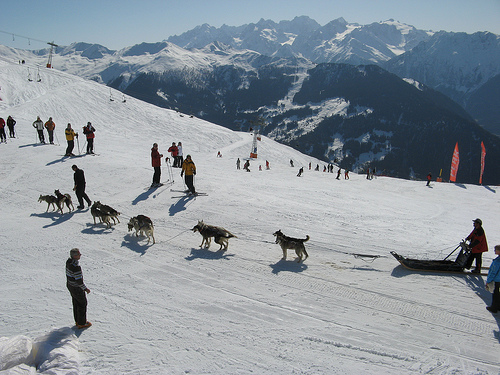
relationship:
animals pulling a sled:
[271, 229, 311, 259] [385, 242, 469, 280]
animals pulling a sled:
[188, 222, 239, 254] [385, 242, 469, 280]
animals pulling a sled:
[271, 229, 311, 259] [390, 250, 462, 274]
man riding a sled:
[462, 218, 486, 275] [390, 243, 472, 272]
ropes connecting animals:
[48, 187, 397, 266] [271, 229, 311, 259]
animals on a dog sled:
[271, 229, 311, 259] [388, 217, 482, 278]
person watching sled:
[64, 247, 98, 326] [391, 246, 472, 272]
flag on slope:
[448, 141, 459, 183] [1, 53, 496, 373]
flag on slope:
[477, 142, 487, 179] [1, 53, 496, 373]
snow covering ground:
[9, 61, 498, 373] [5, 63, 490, 367]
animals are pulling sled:
[37, 191, 71, 216] [391, 254, 468, 272]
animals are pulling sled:
[92, 199, 121, 227] [391, 254, 468, 272]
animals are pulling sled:
[125, 214, 157, 246] [391, 254, 468, 272]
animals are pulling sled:
[188, 222, 239, 254] [391, 254, 468, 272]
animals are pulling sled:
[271, 229, 311, 259] [391, 254, 468, 272]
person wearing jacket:
[483, 244, 499, 343] [483, 257, 498, 317]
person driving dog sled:
[459, 214, 491, 275] [36, 185, 491, 280]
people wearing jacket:
[178, 154, 199, 202] [179, 160, 196, 176]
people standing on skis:
[178, 154, 199, 202] [163, 183, 213, 207]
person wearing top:
[30, 114, 47, 146] [28, 117, 46, 130]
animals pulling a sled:
[271, 229, 311, 259] [384, 240, 469, 288]